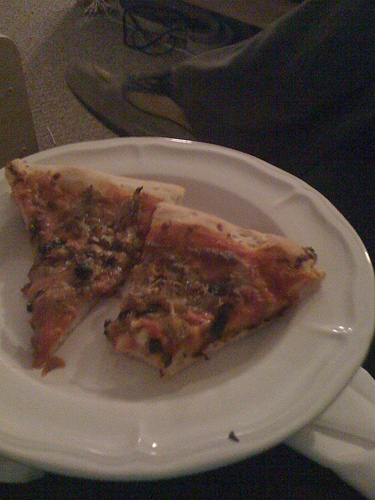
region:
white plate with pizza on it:
[3, 122, 323, 433]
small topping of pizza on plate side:
[215, 415, 251, 456]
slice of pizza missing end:
[107, 211, 306, 392]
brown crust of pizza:
[143, 204, 314, 276]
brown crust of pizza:
[18, 139, 171, 207]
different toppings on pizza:
[25, 205, 120, 338]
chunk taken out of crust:
[286, 236, 330, 294]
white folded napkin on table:
[313, 399, 370, 478]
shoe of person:
[61, 59, 206, 138]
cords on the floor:
[106, 12, 182, 61]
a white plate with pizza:
[0, 129, 372, 476]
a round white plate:
[9, 131, 367, 480]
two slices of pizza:
[7, 157, 311, 364]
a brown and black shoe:
[60, 51, 231, 164]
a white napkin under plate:
[279, 389, 371, 494]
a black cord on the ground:
[114, 7, 202, 64]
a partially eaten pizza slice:
[100, 194, 325, 385]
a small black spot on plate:
[223, 423, 253, 453]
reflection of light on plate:
[148, 419, 164, 453]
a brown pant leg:
[161, 0, 349, 170]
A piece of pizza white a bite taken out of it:
[106, 200, 325, 380]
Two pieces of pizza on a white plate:
[3, 158, 327, 387]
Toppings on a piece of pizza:
[69, 249, 116, 281]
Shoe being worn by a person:
[58, 58, 204, 142]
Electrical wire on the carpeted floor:
[116, 10, 190, 58]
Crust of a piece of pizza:
[152, 201, 328, 285]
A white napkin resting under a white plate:
[290, 365, 374, 494]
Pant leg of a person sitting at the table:
[169, 1, 373, 139]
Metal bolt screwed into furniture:
[3, 85, 16, 96]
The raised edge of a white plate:
[295, 315, 373, 358]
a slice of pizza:
[6, 157, 181, 369]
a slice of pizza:
[113, 199, 320, 373]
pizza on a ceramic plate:
[2, 138, 373, 478]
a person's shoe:
[64, 58, 202, 142]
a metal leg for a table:
[121, 3, 194, 56]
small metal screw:
[5, 85, 10, 94]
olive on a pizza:
[72, 262, 92, 275]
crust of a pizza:
[154, 201, 317, 288]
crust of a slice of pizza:
[9, 158, 184, 211]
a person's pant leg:
[177, 0, 373, 228]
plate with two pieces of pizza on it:
[4, 138, 365, 480]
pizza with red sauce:
[12, 161, 316, 382]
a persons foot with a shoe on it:
[57, 50, 205, 148]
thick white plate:
[1, 153, 368, 476]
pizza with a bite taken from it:
[66, 233, 312, 405]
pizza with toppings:
[10, 157, 323, 382]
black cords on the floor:
[113, 3, 203, 57]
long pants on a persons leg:
[127, 3, 372, 170]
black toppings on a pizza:
[33, 211, 100, 281]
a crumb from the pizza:
[205, 419, 246, 462]